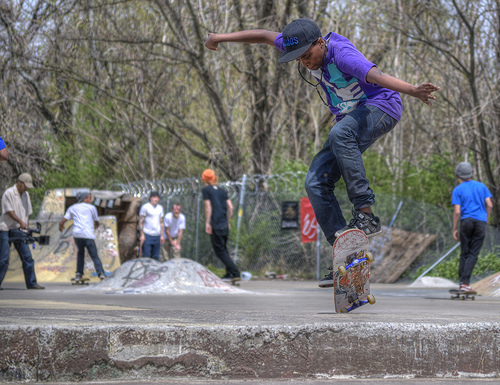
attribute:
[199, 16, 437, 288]
skateboarder — doing a trick